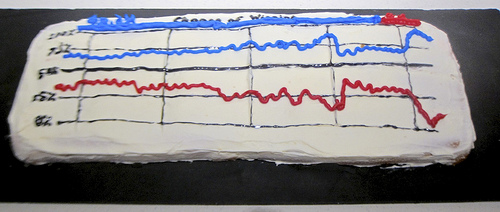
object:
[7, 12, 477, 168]
cake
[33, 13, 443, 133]
graph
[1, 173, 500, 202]
table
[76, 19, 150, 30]
frosting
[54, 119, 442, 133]
lines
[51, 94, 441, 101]
line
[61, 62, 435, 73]
line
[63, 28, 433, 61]
line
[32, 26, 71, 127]
numbers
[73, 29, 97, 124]
lines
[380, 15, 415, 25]
frosting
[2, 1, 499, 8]
wall